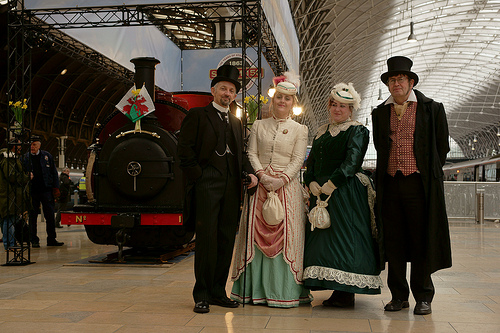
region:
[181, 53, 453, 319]
four people posing together while dressed in Victorian attire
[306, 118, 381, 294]
woman wearing a dark green dress with white lace details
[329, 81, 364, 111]
women wearing a white hat with green ribbon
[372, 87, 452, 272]
man wearing a long dark coat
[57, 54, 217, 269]
a train's engine car on display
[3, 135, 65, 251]
man in a blue uniform talking to someone else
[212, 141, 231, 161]
a watch chain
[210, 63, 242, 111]
man wearing a black top hat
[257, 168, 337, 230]
both women are carrying white purses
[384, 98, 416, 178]
man wearing a red checked waistcoat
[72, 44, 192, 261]
Black and red train.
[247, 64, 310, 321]
Girl in white dress.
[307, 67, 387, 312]
Girl in green dress.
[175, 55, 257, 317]
Man in black hat.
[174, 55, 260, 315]
Man in black suit.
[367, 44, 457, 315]
Man in black hat.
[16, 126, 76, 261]
A police officer.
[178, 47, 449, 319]
A singing group.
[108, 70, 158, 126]
Christmas decoration on a train car.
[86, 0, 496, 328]
A mall at Christmas time.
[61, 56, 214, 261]
black and red train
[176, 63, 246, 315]
man wearing black top hat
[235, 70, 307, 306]
woman wearing white dress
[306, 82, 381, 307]
woman wearing green dress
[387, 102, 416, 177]
red and white checked vest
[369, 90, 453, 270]
black wool trench coat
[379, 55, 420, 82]
black top hat on head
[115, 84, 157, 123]
flags attached to train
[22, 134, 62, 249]
man wearing blue suit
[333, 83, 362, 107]
white and green hat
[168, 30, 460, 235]
people dressed in period clothing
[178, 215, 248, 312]
legs of the man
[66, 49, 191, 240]
front of the train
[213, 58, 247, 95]
top hat on the man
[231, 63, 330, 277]
woman in a dress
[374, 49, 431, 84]
top hat on the man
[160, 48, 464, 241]
four people looking at the camera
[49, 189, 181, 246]
red part of the train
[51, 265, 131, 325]
ground in front of train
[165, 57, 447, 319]
group of people posing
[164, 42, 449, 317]
group of people in costume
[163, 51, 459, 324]
group of people dressed up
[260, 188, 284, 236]
white purse in hand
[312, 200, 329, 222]
small white purse in hand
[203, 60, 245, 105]
black top hat on head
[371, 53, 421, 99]
black top hat on head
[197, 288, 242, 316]
black shoes on man's feet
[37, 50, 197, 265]
front of a black and red train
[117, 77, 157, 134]
white and red flag on train